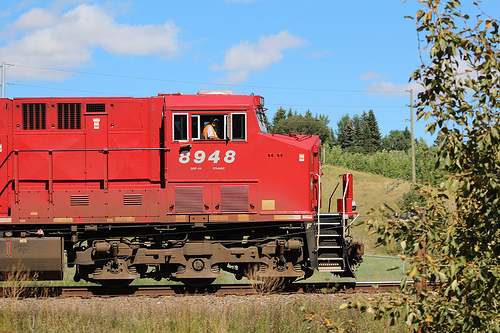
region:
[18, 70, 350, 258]
red train on tracks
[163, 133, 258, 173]
number on side of train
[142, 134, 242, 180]
white numbers on train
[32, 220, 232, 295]
wheels under the train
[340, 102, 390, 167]
green tree next to train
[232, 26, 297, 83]
white cloud in sky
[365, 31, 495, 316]
green leaves on tree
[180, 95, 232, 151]
person in a train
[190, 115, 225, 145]
man wearing the color orange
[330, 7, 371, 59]
blue sky above the land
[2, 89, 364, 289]
red metal train on train tracks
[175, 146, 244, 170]
white number on side of red train tracks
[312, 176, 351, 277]
silver ladder on side of red train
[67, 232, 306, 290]
train wheels on train track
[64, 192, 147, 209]
metal vents on side of red train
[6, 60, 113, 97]
black power lines in sky hanging over train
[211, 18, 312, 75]
white clouds in blue sky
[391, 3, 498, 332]
tall green shrubs in green grass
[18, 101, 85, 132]
two barred windows on side of train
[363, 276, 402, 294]
metal brown train tracks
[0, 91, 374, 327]
a red train on the railway line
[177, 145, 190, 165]
a number on the train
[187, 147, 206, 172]
a number on the train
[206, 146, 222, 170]
a number on the train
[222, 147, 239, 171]
a number on the train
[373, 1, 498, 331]
a tree with green leaves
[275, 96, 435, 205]
bush of trees in the photo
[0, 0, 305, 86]
thin clouds in the sky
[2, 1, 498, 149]
the sky is blue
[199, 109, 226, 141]
a man inside the train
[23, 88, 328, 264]
Engine is red color.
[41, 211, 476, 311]
Engine is on track.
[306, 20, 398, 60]
Sky is blue color.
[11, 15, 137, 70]
Clouds are white color.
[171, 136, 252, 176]
8948 is written on engine.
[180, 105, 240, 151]
One man is driving the engine.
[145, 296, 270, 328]
Grass are brown color.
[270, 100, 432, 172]
Trees are behind the engine.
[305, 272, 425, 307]
Track is brown color.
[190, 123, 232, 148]
Man is wearing orange coat.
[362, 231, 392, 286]
green grass in field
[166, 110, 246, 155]
train window with man in it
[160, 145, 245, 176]
numbers on side of train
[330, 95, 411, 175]
green trees in background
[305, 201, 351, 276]
stairs leading up to train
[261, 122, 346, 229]
front part of train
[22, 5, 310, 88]
white clouds in the blue sky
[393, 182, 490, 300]
leaves on a tree